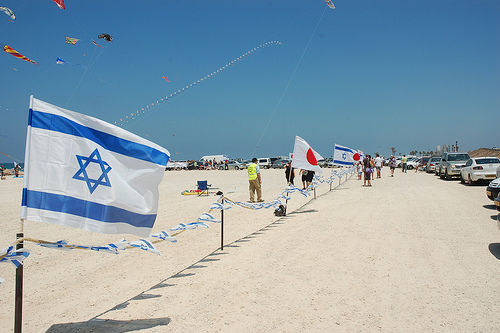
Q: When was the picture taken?
A: Daytime.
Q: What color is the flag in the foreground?
A: Blue and white.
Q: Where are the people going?
A: To the beach.